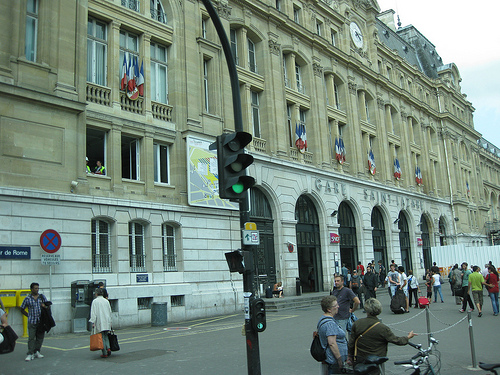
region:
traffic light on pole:
[210, 122, 276, 352]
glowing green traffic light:
[218, 174, 266, 204]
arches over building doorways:
[283, 181, 441, 284]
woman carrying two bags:
[84, 282, 123, 362]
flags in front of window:
[112, 50, 152, 103]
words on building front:
[308, 174, 428, 218]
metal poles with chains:
[448, 308, 486, 367]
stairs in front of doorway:
[292, 283, 332, 314]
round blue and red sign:
[36, 225, 69, 256]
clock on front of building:
[341, 16, 376, 56]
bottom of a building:
[183, 301, 190, 336]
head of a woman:
[317, 302, 344, 316]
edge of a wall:
[90, 229, 100, 257]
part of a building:
[453, 187, 468, 209]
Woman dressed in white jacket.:
[88, 296, 118, 334]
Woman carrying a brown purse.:
[88, 316, 109, 356]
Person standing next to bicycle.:
[343, 297, 444, 374]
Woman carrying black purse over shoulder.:
[306, 314, 335, 373]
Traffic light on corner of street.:
[204, 122, 283, 374]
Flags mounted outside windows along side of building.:
[283, 113, 445, 190]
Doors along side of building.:
[281, 180, 443, 292]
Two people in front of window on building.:
[80, 154, 115, 180]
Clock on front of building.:
[346, 9, 373, 69]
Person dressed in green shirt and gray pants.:
[464, 262, 491, 308]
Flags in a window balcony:
[72, 11, 188, 141]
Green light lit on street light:
[207, 106, 280, 261]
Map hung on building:
[164, 108, 274, 240]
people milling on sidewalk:
[315, 231, 494, 346]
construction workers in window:
[60, 120, 142, 215]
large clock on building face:
[326, 6, 400, 92]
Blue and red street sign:
[17, 194, 124, 346]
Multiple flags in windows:
[273, 74, 480, 218]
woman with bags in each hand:
[60, 259, 150, 370]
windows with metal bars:
[69, 197, 206, 305]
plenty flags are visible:
[120, 61, 178, 112]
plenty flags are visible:
[101, 40, 171, 117]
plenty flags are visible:
[287, 117, 468, 195]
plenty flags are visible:
[275, 115, 367, 205]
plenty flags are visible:
[297, 108, 405, 212]